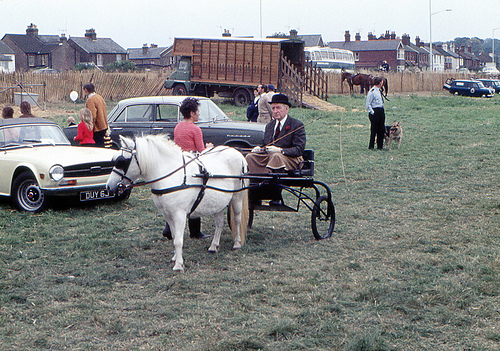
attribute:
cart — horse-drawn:
[244, 147, 333, 237]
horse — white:
[111, 139, 252, 254]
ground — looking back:
[400, 177, 437, 222]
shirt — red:
[74, 121, 95, 144]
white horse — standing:
[98, 128, 253, 268]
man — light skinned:
[230, 78, 350, 187]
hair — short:
[179, 98, 201, 117]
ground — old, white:
[442, 145, 462, 180]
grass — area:
[411, 212, 493, 289]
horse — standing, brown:
[342, 70, 369, 93]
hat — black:
[267, 90, 292, 110]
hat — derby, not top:
[266, 89, 294, 104]